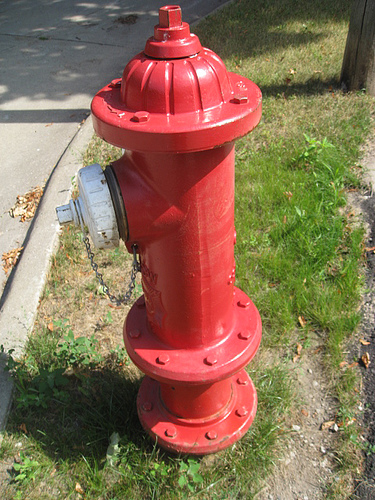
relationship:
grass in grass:
[275, 144, 329, 232] [253, 246, 298, 309]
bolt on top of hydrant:
[151, 5, 201, 36] [89, 14, 296, 417]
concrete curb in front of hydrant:
[21, 90, 248, 395] [49, 4, 274, 458]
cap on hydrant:
[69, 11, 295, 147] [49, 4, 274, 458]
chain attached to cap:
[78, 228, 140, 306] [53, 161, 121, 254]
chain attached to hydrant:
[78, 228, 140, 306] [49, 4, 274, 458]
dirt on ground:
[265, 330, 334, 498] [2, 1, 374, 498]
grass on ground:
[5, 0, 372, 499] [2, 1, 374, 498]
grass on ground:
[50, 371, 91, 456] [2, 1, 374, 498]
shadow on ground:
[1, 356, 185, 463] [2, 1, 374, 498]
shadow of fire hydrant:
[1, 356, 185, 463] [53, 3, 262, 455]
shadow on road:
[0, 98, 98, 140] [3, 1, 171, 460]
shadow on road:
[2, 1, 367, 91] [3, 1, 171, 460]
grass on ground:
[268, 149, 336, 313] [2, 1, 374, 498]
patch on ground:
[260, 332, 344, 498] [2, 1, 374, 498]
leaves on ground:
[13, 193, 37, 218] [2, 1, 374, 498]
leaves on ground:
[361, 242, 372, 253] [2, 1, 374, 498]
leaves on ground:
[340, 351, 371, 369] [2, 1, 374, 498]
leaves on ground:
[291, 341, 302, 360] [2, 1, 374, 498]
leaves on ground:
[297, 313, 307, 328] [2, 1, 374, 498]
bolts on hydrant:
[131, 86, 270, 119] [33, 29, 326, 472]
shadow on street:
[0, 346, 202, 472] [0, 0, 264, 383]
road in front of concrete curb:
[0, 1, 92, 297] [0, 113, 94, 441]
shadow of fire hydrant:
[0, 346, 202, 472] [35, 0, 278, 456]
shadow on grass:
[0, 346, 202, 472] [86, 450, 158, 497]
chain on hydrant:
[78, 228, 140, 306] [49, 4, 274, 458]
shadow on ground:
[0, 346, 202, 472] [31, 280, 371, 495]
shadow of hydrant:
[0, 346, 202, 472] [47, 4, 323, 460]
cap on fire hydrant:
[55, 161, 119, 252] [89, 2, 264, 458]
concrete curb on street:
[0, 113, 94, 441] [1, 10, 129, 243]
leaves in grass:
[9, 183, 43, 223] [264, 107, 363, 258]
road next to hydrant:
[0, 1, 92, 297] [49, 4, 274, 458]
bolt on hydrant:
[163, 424, 173, 441] [59, 14, 341, 372]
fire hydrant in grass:
[54, 4, 262, 456] [227, 86, 365, 317]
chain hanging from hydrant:
[82, 230, 141, 307] [49, 4, 274, 458]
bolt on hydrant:
[157, 5, 182, 29] [56, 3, 261, 453]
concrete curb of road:
[0, 113, 94, 441] [0, 1, 92, 297]